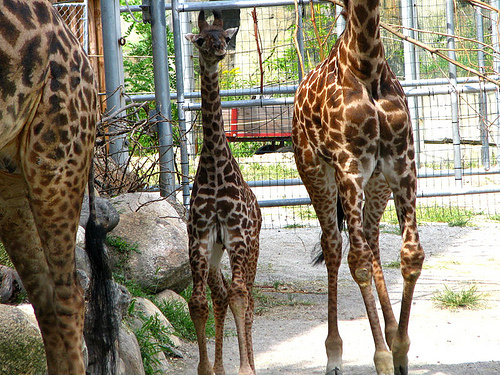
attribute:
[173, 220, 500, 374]
ground — white, gravel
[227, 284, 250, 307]
knee — knobby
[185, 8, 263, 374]
giraffe — small, baby, cute, walking, high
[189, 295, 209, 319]
knee — knobby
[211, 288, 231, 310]
knee — knobby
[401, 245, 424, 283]
knee — knobby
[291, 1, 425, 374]
giraffe — adult size, young, adult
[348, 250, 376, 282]
knee — knobby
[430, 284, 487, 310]
grass — growing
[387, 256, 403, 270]
grass — growing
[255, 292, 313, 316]
grass — growing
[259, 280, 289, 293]
grass — growing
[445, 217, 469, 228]
grass — growing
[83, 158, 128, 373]
tail — long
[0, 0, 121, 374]
giraffe — adult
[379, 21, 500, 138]
branch — dry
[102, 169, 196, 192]
branch — dry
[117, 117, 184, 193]
branch — dry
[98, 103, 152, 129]
branch — dry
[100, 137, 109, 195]
branch — dry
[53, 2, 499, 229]
fence — mesh, gray, metal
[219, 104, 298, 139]
crate — wooden, red trimmed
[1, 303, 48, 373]
rock — large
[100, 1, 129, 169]
pole — metal, gray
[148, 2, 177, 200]
pole — metal, gray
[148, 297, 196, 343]
vegetation — growing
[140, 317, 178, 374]
vegetation — growing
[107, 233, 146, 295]
vegetation — growing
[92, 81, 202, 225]
branches — leafless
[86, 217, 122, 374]
hair — long, black